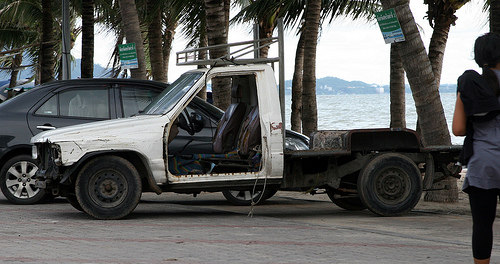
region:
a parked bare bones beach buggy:
[27, 18, 464, 215]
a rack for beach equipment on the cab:
[172, 17, 290, 140]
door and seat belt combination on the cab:
[244, 130, 277, 223]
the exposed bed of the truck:
[288, 106, 461, 179]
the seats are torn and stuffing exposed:
[186, 97, 260, 170]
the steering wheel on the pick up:
[167, 102, 196, 142]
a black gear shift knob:
[171, 130, 201, 166]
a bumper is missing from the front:
[26, 130, 72, 199]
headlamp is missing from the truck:
[43, 137, 70, 170]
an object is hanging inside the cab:
[188, 93, 230, 130]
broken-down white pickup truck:
[27, 24, 473, 209]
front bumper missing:
[24, 128, 89, 200]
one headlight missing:
[26, 134, 81, 189]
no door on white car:
[145, 57, 282, 191]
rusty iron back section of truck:
[292, 118, 424, 163]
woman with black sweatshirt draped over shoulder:
[449, 67, 497, 259]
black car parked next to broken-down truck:
[6, 69, 293, 165]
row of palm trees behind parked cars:
[1, 0, 497, 190]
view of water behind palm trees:
[234, 80, 497, 174]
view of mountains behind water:
[261, 65, 475, 96]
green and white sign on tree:
[371, 4, 407, 49]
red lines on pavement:
[3, 185, 499, 261]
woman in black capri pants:
[446, 77, 497, 261]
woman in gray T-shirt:
[443, 69, 497, 255]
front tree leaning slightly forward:
[376, 6, 463, 166]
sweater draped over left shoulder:
[451, 71, 499, 168]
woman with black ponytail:
[471, 35, 496, 97]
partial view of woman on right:
[452, 30, 499, 260]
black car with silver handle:
[1, 73, 153, 145]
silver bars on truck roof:
[168, 32, 283, 65]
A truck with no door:
[171, 65, 262, 178]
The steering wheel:
[179, 107, 196, 137]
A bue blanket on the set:
[177, 145, 254, 180]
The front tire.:
[65, 158, 155, 220]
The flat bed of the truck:
[280, 118, 457, 192]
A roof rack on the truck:
[165, 23, 291, 67]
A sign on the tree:
[370, 0, 411, 50]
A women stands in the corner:
[442, 20, 498, 262]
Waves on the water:
[327, 91, 378, 118]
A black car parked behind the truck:
[0, 81, 136, 199]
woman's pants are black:
[461, 173, 499, 262]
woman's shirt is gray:
[442, 98, 497, 185]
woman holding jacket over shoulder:
[444, 55, 497, 140]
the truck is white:
[23, 2, 303, 219]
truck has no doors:
[134, 47, 276, 198]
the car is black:
[0, 43, 225, 191]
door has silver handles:
[31, 107, 76, 147]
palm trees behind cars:
[0, 0, 483, 194]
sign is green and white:
[371, 4, 409, 56]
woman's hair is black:
[467, 23, 497, 60]